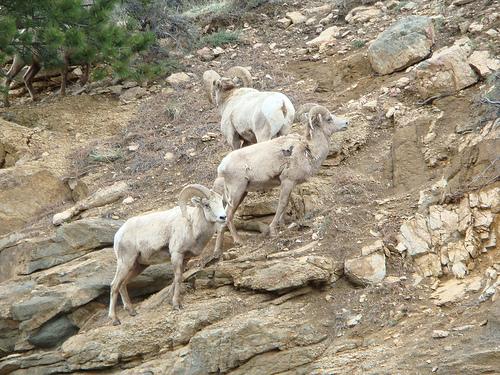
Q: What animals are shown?
A: Ram.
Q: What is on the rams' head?
A: Horns.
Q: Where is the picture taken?
A: A mountain.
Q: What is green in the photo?
A: A tree.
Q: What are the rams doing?
A: Climbing.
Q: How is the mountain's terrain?
A: Rocky.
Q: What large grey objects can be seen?
A: Boulders.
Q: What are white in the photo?
A: Rams.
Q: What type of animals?
A: Goats.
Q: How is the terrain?
A: Rocky.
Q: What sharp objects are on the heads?
A: Horns.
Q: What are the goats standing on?
A: Rocks.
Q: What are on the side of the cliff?
A: Rams.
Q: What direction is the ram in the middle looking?
A: Up.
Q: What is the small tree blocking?
A: Ram.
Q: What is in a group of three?
A: Rams.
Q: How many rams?
A: Three.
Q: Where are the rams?
A: On rocks.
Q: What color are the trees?
A: Green.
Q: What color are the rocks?
A: Tan.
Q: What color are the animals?
A: White.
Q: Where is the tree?
A: On cliff.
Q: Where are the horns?
A: On rams.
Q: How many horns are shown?
A: Six.